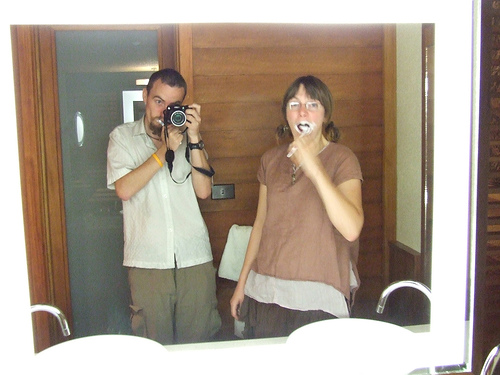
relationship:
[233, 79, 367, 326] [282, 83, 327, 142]
woman has woman's face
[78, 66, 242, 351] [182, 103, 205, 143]
camera in hand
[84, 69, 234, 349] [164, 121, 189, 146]
man has hand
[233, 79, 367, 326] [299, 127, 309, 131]
woman brushing teeth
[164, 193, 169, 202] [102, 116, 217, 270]
button on shirt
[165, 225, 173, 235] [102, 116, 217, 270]
button on shirt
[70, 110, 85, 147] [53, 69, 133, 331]
light on wall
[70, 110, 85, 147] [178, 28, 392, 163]
light on wall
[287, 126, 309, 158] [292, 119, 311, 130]
toothbrush in mouth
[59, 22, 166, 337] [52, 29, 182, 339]
paint on wall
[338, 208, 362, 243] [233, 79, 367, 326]
elbow of woman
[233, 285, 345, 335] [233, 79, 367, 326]
pants of woman